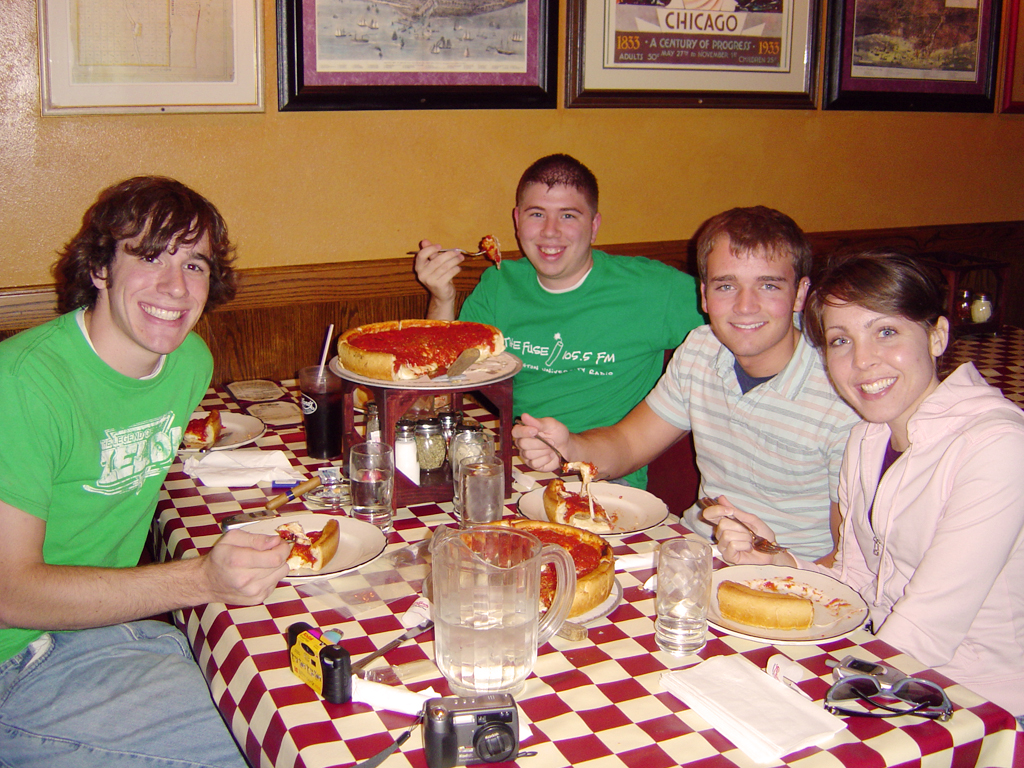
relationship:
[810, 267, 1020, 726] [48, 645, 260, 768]
person sitting down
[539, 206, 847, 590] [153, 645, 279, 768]
person sitting down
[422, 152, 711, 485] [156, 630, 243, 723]
person sitting down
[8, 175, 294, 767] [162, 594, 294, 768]
person sitting down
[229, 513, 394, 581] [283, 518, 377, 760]
plate for dining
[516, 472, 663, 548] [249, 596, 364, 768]
plate for dining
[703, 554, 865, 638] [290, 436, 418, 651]
plate for dining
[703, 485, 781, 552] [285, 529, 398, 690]
utensil for dining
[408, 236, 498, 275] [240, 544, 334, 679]
utensil for dining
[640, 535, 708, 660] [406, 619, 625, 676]
vessel for drinking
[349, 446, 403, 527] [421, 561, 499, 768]
vessel for drinking